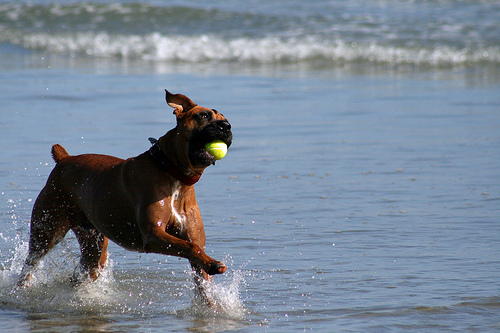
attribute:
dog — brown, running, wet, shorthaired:
[47, 90, 245, 309]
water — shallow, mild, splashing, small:
[313, 138, 429, 239]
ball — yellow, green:
[195, 126, 226, 166]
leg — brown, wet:
[143, 227, 230, 288]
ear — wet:
[167, 82, 209, 120]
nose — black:
[217, 117, 235, 134]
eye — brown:
[194, 109, 212, 138]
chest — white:
[171, 196, 200, 235]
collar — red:
[155, 149, 205, 195]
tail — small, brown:
[41, 147, 62, 172]